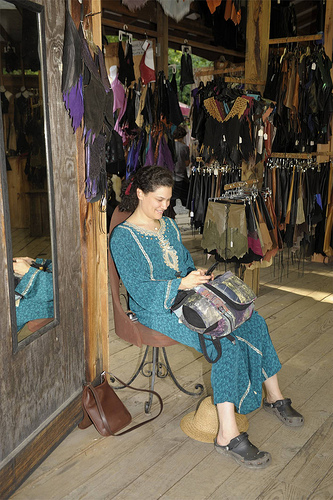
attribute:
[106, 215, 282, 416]
dress — blue, reflecting, decorative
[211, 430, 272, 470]
clog — dirty, black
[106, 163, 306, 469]
woman — middle aged, sitting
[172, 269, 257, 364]
handbag — colorful, multi-color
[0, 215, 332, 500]
floor — wooden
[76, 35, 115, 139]
vest — leather, hanging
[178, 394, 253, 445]
hat — tan, woven, wicker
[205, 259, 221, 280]
phone — black, small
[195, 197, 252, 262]
skirt — green, hanging, brown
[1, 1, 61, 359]
mirror — framed, long, large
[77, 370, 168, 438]
purse — brown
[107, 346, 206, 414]
bottom — iron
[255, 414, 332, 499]
plank — wooden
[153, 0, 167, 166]
post — brown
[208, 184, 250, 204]
hanger — plastic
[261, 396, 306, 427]
crocket — black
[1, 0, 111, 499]
wall — wooden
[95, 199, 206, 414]
chair — brown